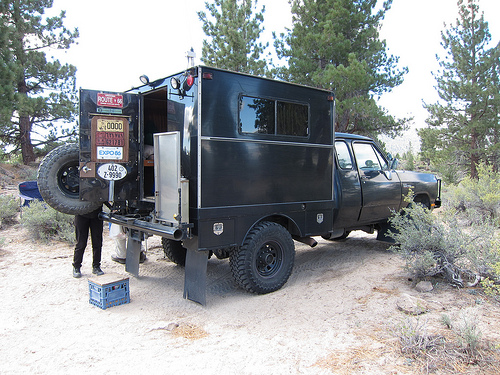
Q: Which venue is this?
A: This is a road.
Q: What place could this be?
A: It is a road.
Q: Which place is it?
A: It is a road.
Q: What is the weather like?
A: It is clear.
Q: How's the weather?
A: It is clear.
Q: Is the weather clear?
A: Yes, it is clear.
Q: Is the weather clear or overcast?
A: It is clear.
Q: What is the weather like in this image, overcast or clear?
A: It is clear.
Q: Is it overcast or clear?
A: It is clear.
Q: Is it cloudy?
A: No, it is clear.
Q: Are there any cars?
A: No, there are no cars.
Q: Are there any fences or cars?
A: No, there are no cars or fences.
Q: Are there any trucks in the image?
A: Yes, there is a truck.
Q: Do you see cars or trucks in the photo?
A: Yes, there is a truck.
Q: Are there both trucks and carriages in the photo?
A: No, there is a truck but no carriages.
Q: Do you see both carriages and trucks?
A: No, there is a truck but no carriages.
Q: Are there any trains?
A: No, there are no trains.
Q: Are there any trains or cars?
A: No, there are no trains or cars.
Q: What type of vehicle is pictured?
A: The vehicle is a truck.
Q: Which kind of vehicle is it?
A: The vehicle is a truck.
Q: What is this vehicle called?
A: This is a truck.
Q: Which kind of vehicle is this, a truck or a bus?
A: This is a truck.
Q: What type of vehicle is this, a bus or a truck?
A: This is a truck.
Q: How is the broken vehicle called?
A: The vehicle is a truck.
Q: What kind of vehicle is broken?
A: The vehicle is a truck.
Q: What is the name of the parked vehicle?
A: The vehicle is a truck.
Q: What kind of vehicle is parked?
A: The vehicle is a truck.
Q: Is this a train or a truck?
A: This is a truck.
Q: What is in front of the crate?
A: The truck is in front of the crate.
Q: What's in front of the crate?
A: The truck is in front of the crate.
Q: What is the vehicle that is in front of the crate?
A: The vehicle is a truck.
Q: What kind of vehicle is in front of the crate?
A: The vehicle is a truck.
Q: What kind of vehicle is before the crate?
A: The vehicle is a truck.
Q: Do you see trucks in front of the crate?
A: Yes, there is a truck in front of the crate.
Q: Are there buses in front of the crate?
A: No, there is a truck in front of the crate.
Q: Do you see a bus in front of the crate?
A: No, there is a truck in front of the crate.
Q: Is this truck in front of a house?
A: No, the truck is in front of the crate.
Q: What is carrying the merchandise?
A: The truck is carrying the merchandise.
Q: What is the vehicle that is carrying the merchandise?
A: The vehicle is a truck.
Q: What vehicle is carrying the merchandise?
A: The vehicle is a truck.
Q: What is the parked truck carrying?
A: The truck is carrying merchandise.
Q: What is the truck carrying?
A: The truck is carrying merchandise.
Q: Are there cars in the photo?
A: No, there are no cars.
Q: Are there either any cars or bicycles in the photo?
A: No, there are no cars or bicycles.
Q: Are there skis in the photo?
A: No, there are no skis.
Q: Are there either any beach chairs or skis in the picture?
A: No, there are no skis or beach chairs.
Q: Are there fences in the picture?
A: No, there are no fences.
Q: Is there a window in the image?
A: Yes, there is a window.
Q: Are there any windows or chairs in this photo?
A: Yes, there is a window.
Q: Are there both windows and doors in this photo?
A: Yes, there are both a window and a door.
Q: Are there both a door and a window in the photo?
A: Yes, there are both a window and a door.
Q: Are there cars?
A: No, there are no cars.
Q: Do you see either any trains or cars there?
A: No, there are no cars or trains.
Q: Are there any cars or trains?
A: No, there are no cars or trains.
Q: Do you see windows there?
A: Yes, there are windows.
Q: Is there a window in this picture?
A: Yes, there are windows.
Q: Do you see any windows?
A: Yes, there are windows.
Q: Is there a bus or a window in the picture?
A: Yes, there are windows.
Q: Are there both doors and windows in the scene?
A: Yes, there are both windows and doors.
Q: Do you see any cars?
A: No, there are no cars.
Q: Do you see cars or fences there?
A: No, there are no cars or fences.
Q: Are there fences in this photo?
A: No, there are no fences.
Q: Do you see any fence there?
A: No, there are no fences.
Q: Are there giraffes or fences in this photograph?
A: No, there are no fences or giraffes.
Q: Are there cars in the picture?
A: No, there are no cars.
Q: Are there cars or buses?
A: No, there are no cars or buses.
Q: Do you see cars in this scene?
A: No, there are no cars.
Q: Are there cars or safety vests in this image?
A: No, there are no cars or safety vests.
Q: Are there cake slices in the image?
A: No, there are no cake slices.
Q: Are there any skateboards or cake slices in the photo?
A: No, there are no cake slices or skateboards.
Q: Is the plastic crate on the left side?
A: Yes, the crate is on the left of the image.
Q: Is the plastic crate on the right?
A: No, the crate is on the left of the image.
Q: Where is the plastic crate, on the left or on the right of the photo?
A: The crate is on the left of the image.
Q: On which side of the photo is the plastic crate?
A: The crate is on the left of the image.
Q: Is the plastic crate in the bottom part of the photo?
A: Yes, the crate is in the bottom of the image.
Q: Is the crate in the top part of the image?
A: No, the crate is in the bottom of the image.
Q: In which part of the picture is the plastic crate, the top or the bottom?
A: The crate is in the bottom of the image.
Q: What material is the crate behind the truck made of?
A: The crate is made of plastic.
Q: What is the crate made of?
A: The crate is made of plastic.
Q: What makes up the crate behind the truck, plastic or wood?
A: The crate is made of plastic.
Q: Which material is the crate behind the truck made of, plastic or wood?
A: The crate is made of plastic.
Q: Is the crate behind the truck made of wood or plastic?
A: The crate is made of plastic.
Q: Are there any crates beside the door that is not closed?
A: Yes, there is a crate beside the door.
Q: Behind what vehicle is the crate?
A: The crate is behind the truck.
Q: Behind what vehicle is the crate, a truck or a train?
A: The crate is behind a truck.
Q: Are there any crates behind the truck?
A: Yes, there is a crate behind the truck.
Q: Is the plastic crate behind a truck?
A: Yes, the crate is behind a truck.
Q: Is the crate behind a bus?
A: No, the crate is behind a truck.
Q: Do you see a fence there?
A: No, there are no fences.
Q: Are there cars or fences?
A: No, there are no fences or cars.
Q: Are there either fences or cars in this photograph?
A: No, there are no fences or cars.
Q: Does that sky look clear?
A: Yes, the sky is clear.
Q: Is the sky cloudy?
A: No, the sky is clear.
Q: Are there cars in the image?
A: No, there are no cars.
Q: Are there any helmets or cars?
A: No, there are no cars or helmets.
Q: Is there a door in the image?
A: Yes, there is a door.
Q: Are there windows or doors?
A: Yes, there is a door.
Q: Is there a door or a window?
A: Yes, there is a door.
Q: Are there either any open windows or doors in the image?
A: Yes, there is an open door.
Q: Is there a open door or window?
A: Yes, there is an open door.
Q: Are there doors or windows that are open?
A: Yes, the door is open.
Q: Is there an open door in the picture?
A: Yes, there is an open door.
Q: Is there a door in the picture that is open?
A: Yes, there is a door that is open.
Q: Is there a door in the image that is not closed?
A: Yes, there is a open door.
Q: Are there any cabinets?
A: No, there are no cabinets.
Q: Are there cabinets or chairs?
A: No, there are no cabinets or chairs.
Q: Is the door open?
A: Yes, the door is open.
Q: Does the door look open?
A: Yes, the door is open.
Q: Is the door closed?
A: No, the door is open.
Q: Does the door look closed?
A: No, the door is open.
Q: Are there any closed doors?
A: No, there is a door but it is open.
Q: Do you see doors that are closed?
A: No, there is a door but it is open.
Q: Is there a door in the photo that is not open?
A: No, there is a door but it is open.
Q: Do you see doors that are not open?
A: No, there is a door but it is open.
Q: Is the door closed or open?
A: The door is open.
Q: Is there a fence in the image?
A: No, there are no fences.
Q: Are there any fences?
A: No, there are no fences.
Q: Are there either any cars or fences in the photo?
A: No, there are no fences or cars.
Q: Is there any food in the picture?
A: No, there is no food.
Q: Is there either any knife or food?
A: No, there are no food or knives.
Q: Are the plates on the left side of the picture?
A: Yes, the plates are on the left of the image.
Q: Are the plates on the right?
A: No, the plates are on the left of the image.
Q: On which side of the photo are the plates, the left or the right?
A: The plates are on the left of the image.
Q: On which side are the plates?
A: The plates are on the left of the image.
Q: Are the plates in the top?
A: Yes, the plates are in the top of the image.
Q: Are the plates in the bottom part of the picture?
A: No, the plates are in the top of the image.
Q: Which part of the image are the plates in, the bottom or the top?
A: The plates are in the top of the image.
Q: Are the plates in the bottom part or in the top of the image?
A: The plates are in the top of the image.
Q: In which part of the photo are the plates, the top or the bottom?
A: The plates are in the top of the image.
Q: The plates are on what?
A: The plates are on the door.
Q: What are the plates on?
A: The plates are on the door.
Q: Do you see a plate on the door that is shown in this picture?
A: Yes, there are plates on the door.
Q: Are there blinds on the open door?
A: No, there are plates on the door.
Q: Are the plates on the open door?
A: Yes, the plates are on the door.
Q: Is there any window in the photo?
A: Yes, there is a window.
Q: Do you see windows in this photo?
A: Yes, there is a window.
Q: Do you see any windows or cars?
A: Yes, there is a window.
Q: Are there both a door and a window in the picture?
A: Yes, there are both a window and a door.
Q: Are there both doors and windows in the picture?
A: Yes, there are both a window and a door.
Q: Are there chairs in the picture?
A: No, there are no chairs.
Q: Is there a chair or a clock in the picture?
A: No, there are no chairs or clocks.